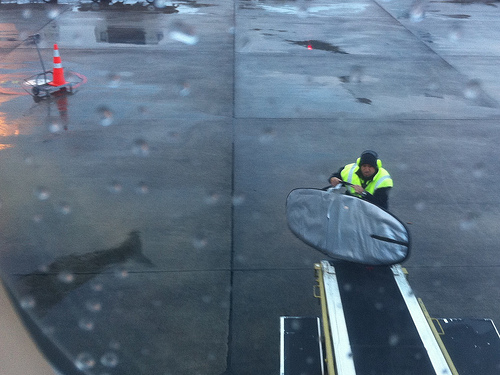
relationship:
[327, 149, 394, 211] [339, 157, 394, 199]
employee wearing a coat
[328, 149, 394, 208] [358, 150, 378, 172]
employee wearing a cap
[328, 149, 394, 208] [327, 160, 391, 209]
employee wearing a coat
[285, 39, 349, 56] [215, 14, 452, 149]
puddle on pavement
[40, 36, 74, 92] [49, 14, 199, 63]
cone in front of puddle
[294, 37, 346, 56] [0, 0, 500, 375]
puddle on paved area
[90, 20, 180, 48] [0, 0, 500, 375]
puddle on paved area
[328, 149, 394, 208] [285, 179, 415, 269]
employee lifting a bag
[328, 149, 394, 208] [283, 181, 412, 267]
employee loading up bag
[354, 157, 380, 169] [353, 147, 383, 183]
earmuffs on head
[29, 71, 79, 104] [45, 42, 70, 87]
dolly holding cone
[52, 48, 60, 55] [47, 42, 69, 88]
stripe on traffic cone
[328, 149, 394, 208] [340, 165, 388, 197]
employee wearing vest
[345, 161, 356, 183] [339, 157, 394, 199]
reflective stripe on coat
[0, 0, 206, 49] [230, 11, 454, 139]
puddle on pavement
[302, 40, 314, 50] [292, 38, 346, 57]
red light reflected puddle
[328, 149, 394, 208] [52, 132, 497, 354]
employee in water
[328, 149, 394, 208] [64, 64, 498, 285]
employee in water